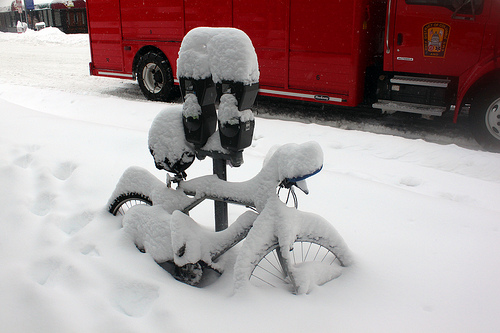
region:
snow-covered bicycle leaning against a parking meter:
[106, 30, 359, 286]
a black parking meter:
[177, 25, 257, 227]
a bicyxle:
[110, 145, 354, 287]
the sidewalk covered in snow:
[10, 159, 484, 331]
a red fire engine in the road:
[85, 3, 499, 136]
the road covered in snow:
[4, 47, 499, 164]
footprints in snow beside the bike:
[18, 156, 158, 318]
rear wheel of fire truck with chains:
[136, 56, 170, 100]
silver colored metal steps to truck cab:
[374, 77, 452, 119]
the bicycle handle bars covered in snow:
[274, 146, 322, 193]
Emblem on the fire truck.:
[417, 13, 459, 66]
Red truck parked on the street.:
[286, 10, 484, 106]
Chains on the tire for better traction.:
[125, 48, 180, 98]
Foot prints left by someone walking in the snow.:
[20, 126, 110, 302]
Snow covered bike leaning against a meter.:
[112, 133, 366, 284]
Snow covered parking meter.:
[175, 10, 262, 146]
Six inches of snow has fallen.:
[170, 18, 263, 87]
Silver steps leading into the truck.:
[370, 67, 452, 123]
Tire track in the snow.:
[5, 31, 84, 93]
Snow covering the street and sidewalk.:
[364, 144, 476, 306]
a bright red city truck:
[80, 2, 489, 129]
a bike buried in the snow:
[105, 162, 345, 296]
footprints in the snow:
[6, 137, 98, 233]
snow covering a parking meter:
[174, 30, 257, 80]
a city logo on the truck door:
[414, 13, 452, 56]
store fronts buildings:
[3, 1, 82, 31]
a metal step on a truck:
[376, 96, 444, 119]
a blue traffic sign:
[26, 1, 41, 26]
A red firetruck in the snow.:
[82, 1, 499, 138]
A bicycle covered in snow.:
[96, 138, 362, 298]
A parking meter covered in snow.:
[167, 22, 272, 252]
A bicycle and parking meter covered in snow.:
[82, 19, 374, 320]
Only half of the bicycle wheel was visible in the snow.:
[232, 205, 364, 305]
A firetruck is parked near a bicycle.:
[69, 2, 496, 317]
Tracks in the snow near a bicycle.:
[4, 139, 382, 331]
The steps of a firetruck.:
[369, 67, 463, 134]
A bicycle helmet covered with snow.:
[144, 96, 201, 178]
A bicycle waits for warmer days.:
[1, 0, 493, 327]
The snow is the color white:
[8, 112, 60, 317]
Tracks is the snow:
[15, 138, 161, 325]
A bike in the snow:
[110, 139, 368, 304]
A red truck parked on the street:
[64, 0, 497, 149]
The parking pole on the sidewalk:
[169, 25, 266, 168]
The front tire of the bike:
[227, 207, 359, 300]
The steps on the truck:
[368, 69, 458, 124]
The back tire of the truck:
[129, 48, 178, 103]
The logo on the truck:
[417, 15, 454, 62]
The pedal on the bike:
[160, 208, 209, 272]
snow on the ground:
[3, 63, 496, 319]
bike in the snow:
[85, 88, 355, 298]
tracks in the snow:
[8, 103, 170, 331]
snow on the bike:
[103, 102, 351, 297]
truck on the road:
[76, 8, 498, 135]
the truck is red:
[63, 3, 495, 128]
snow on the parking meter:
[163, 25, 270, 167]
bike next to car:
[51, 26, 382, 305]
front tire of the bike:
[226, 213, 378, 290]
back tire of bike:
[63, 162, 203, 287]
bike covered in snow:
[73, 134, 385, 299]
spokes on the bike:
[241, 231, 346, 311]